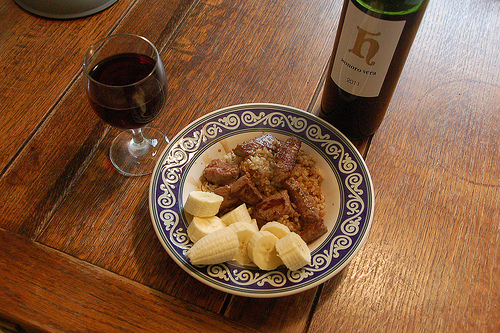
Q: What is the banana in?
A: Bowl.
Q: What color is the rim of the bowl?
A: Blue.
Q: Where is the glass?
A: Beside the bowl.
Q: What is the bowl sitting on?
A: Table.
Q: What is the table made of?
A: Wood.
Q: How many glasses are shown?
A: 1.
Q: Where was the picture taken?
A: At a table.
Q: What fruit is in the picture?
A: Banana.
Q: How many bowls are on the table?
A: 1.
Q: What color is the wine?
A: Red.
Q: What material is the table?
A: Wood.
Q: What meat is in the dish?
A: Sausage.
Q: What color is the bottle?
A: Green.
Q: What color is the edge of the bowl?
A: Blue.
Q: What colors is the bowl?
A: Blue and white.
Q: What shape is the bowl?
A: Round.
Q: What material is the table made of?
A: Wood.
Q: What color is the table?
A: Brown.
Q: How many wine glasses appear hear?
A: One.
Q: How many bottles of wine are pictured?
A: One.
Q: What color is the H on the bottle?
A: Gold.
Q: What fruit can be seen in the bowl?
A: Bananas.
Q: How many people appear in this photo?
A: Zero.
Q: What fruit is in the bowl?
A: Banana.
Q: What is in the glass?
A: Wine.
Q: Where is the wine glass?
A: Next to the bowl.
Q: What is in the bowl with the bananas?
A: Meat and rice.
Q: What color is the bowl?
A: Blue and white.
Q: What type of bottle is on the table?
A: Wine.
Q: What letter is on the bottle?
A: H.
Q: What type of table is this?
A: Wood.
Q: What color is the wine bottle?
A: Green.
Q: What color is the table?
A: Brown.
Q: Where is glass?
A: On table.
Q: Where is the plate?
A: On a table.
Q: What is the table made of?
A: Wood.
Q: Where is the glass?
A: To the left of the plate.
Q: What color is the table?
A: Brown.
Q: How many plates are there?
A: One.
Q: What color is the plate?
A: White and blue.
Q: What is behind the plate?
A: A wine bottle.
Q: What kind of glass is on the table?
A: A wine glass.